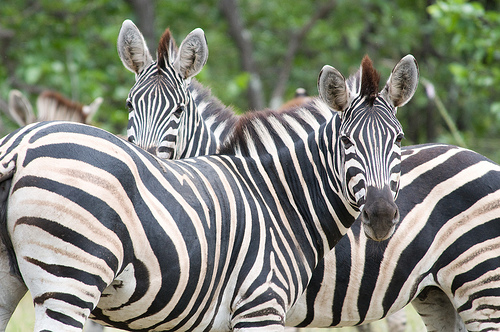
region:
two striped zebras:
[0, 25, 492, 326]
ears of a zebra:
[113, 13, 210, 79]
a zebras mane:
[351, 53, 381, 105]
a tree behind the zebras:
[213, 2, 328, 94]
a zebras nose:
[361, 189, 405, 243]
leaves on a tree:
[435, 0, 493, 90]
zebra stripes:
[259, 158, 321, 269]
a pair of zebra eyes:
[330, 123, 407, 156]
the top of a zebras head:
[9, 91, 89, 123]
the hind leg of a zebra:
[4, 164, 127, 328]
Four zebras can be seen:
[0, 11, 498, 330]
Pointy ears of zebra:
[311, 53, 424, 113]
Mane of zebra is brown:
[342, 51, 384, 103]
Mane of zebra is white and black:
[187, 76, 239, 138]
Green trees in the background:
[2, 6, 498, 105]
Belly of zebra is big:
[313, 253, 422, 330]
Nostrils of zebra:
[357, 199, 405, 228]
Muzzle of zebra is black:
[357, 186, 402, 248]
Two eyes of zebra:
[122, 94, 187, 120]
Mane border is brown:
[30, 86, 94, 127]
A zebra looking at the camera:
[2, 50, 418, 329]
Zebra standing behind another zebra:
[112, 12, 219, 160]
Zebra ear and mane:
[5, 78, 86, 128]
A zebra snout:
[357, 183, 398, 244]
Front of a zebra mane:
[356, 52, 378, 110]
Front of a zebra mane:
[153, 27, 173, 69]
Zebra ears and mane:
[315, 53, 420, 113]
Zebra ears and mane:
[113, 11, 207, 84]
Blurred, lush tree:
[208, 0, 311, 100]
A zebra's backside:
[5, 120, 135, 328]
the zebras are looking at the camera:
[32, 32, 408, 321]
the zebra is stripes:
[261, 35, 430, 264]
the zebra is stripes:
[62, 50, 496, 330]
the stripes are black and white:
[16, 66, 419, 318]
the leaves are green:
[26, 17, 88, 102]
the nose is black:
[312, 170, 452, 250]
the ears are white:
[93, 14, 274, 124]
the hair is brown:
[147, 27, 183, 79]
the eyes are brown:
[310, 120, 433, 165]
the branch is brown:
[217, 5, 288, 106]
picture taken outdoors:
[44, 32, 426, 224]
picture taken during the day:
[54, 25, 475, 190]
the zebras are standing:
[79, 65, 410, 277]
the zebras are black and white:
[79, 91, 461, 271]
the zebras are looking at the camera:
[89, 42, 421, 212]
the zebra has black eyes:
[133, 94, 442, 205]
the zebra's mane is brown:
[149, 32, 181, 66]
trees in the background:
[64, 17, 418, 117]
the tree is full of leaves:
[90, 38, 447, 120]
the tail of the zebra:
[5, 132, 21, 206]